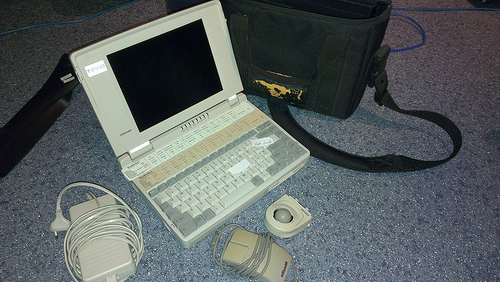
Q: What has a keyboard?
A: Laptop.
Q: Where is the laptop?
A: On the floor.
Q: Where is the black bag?
A: On the floor.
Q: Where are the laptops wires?
A: On the floor.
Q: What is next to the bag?
A: Laptop.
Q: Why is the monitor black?
A: It's off.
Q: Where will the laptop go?
A: In the bag.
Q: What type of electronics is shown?
A: Laptop.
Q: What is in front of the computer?
A: Mouse.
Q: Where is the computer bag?
A: Beside the laptop.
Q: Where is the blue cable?
A: Background.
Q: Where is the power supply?
A: Bottom left corner.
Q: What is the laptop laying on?
A: Table.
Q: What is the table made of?
A: Marble.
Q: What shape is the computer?
A: Square.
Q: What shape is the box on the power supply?
A: Rectangle.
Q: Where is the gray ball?
A: Beside the mouse.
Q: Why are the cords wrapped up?
A: For traveling.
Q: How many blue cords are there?
A: 1.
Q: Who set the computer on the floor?
A: Computer owner.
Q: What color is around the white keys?
A: Grey.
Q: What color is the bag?
A: Black.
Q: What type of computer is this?
A: Laptop.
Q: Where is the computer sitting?
A: Floor.